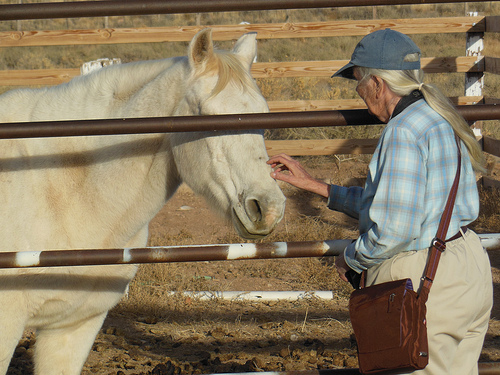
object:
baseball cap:
[331, 29, 425, 81]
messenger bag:
[348, 130, 464, 375]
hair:
[193, 43, 257, 100]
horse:
[0, 26, 286, 374]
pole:
[171, 290, 333, 299]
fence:
[0, 0, 499, 267]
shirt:
[324, 89, 479, 275]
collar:
[391, 88, 423, 119]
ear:
[188, 24, 215, 68]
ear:
[232, 31, 260, 68]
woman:
[269, 28, 497, 374]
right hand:
[264, 152, 316, 191]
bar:
[0, 232, 499, 269]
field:
[2, 0, 499, 374]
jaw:
[229, 208, 267, 241]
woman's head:
[353, 29, 422, 123]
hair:
[359, 54, 491, 177]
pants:
[367, 225, 498, 375]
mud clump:
[242, 353, 264, 369]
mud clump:
[152, 360, 177, 374]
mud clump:
[331, 350, 357, 367]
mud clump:
[209, 324, 229, 340]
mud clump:
[277, 346, 298, 359]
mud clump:
[257, 318, 297, 331]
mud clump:
[211, 356, 234, 374]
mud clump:
[112, 337, 146, 359]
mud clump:
[142, 315, 158, 324]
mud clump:
[173, 332, 200, 344]